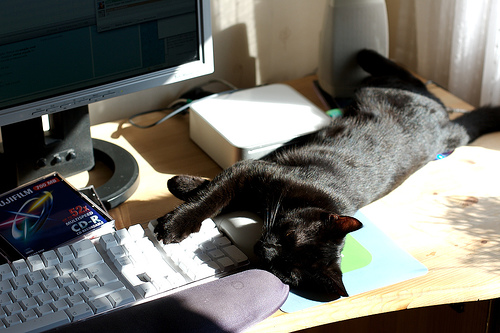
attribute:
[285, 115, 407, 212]
cat — black, sleeping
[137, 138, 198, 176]
table — brown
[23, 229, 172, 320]
keyboard — white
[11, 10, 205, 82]
monitor — on, off, silver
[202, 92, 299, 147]
router — white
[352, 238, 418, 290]
mouse pad — green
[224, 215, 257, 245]
mouse — white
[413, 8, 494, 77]
curtain — white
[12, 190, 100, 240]
case — blue, plastic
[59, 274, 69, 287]
key — white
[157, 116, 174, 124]
cord — gray